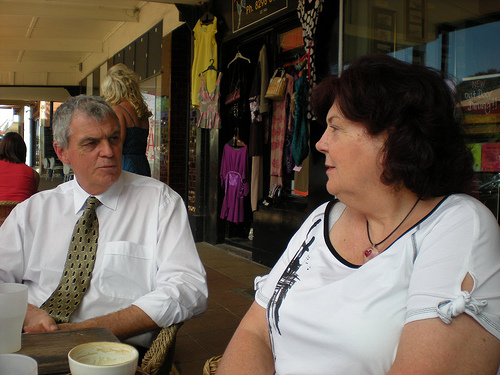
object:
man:
[0, 94, 208, 344]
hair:
[50, 92, 119, 148]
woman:
[99, 61, 152, 177]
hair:
[102, 62, 156, 119]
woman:
[211, 55, 499, 374]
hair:
[310, 54, 474, 200]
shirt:
[253, 194, 498, 373]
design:
[266, 212, 322, 367]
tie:
[40, 197, 103, 326]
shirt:
[0, 169, 211, 351]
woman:
[0, 131, 40, 201]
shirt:
[0, 161, 40, 202]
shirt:
[218, 143, 250, 224]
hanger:
[228, 126, 245, 149]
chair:
[138, 322, 182, 375]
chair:
[200, 354, 228, 374]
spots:
[80, 245, 87, 252]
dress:
[188, 16, 219, 108]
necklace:
[364, 190, 426, 261]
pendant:
[361, 246, 376, 260]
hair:
[0, 131, 28, 165]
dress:
[295, 0, 327, 122]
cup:
[68, 340, 142, 374]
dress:
[114, 102, 153, 177]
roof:
[0, 0, 163, 87]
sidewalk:
[175, 242, 272, 374]